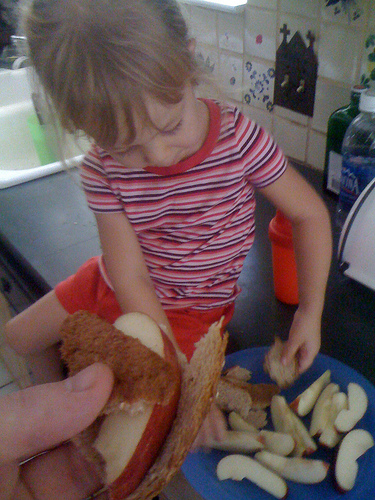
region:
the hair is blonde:
[22, 0, 226, 190]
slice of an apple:
[216, 451, 284, 497]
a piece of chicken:
[60, 313, 177, 410]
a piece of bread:
[125, 317, 226, 499]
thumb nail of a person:
[69, 363, 100, 391]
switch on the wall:
[279, 75, 288, 86]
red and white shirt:
[95, 92, 295, 284]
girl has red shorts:
[81, 254, 250, 411]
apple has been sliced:
[237, 354, 367, 499]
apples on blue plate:
[227, 322, 321, 470]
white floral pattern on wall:
[205, 8, 282, 117]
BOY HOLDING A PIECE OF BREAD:
[261, 337, 294, 386]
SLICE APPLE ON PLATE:
[217, 461, 278, 498]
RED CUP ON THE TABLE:
[271, 216, 296, 303]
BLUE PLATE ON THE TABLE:
[335, 359, 348, 379]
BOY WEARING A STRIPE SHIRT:
[190, 196, 239, 256]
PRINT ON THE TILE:
[325, 6, 358, 24]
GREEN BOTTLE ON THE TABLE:
[328, 100, 344, 197]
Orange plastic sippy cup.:
[268, 207, 300, 306]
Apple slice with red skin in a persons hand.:
[93, 310, 178, 497]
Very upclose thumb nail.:
[61, 363, 101, 392]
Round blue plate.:
[181, 343, 373, 498]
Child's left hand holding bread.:
[280, 309, 321, 376]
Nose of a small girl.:
[139, 137, 171, 166]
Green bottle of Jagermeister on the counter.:
[319, 83, 369, 202]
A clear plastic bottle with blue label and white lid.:
[332, 87, 373, 227]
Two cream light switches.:
[279, 72, 305, 92]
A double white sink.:
[0, 65, 100, 189]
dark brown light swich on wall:
[272, 24, 317, 117]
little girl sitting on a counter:
[3, 10, 332, 382]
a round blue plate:
[179, 349, 373, 498]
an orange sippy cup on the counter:
[268, 206, 301, 306]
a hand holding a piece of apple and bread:
[4, 315, 222, 498]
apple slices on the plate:
[210, 370, 370, 495]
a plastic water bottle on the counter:
[333, 91, 373, 223]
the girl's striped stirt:
[80, 96, 286, 308]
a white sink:
[2, 70, 97, 191]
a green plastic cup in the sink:
[27, 112, 63, 167]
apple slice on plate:
[216, 451, 281, 493]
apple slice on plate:
[261, 438, 333, 486]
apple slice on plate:
[337, 423, 362, 485]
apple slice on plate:
[235, 412, 295, 455]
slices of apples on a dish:
[225, 383, 373, 493]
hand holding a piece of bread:
[257, 307, 324, 390]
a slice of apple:
[211, 450, 290, 496]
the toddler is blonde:
[15, 0, 307, 293]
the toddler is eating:
[22, 0, 232, 219]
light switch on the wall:
[259, 30, 319, 120]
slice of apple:
[325, 426, 372, 490]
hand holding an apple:
[15, 313, 183, 478]